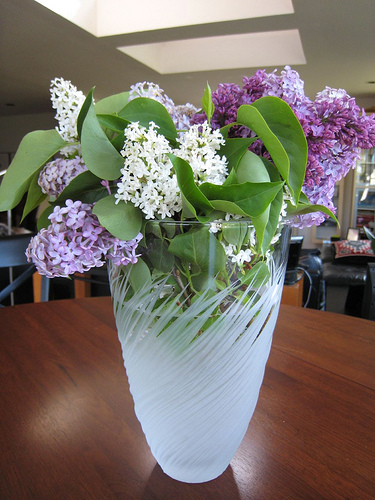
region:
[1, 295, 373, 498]
The table has a wooden top.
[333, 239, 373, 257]
Red designed pillow on black couch.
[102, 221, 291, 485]
The vase has frosted glass details.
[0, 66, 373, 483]
The vase is full of flowers.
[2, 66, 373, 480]
Purple and white flowers in a vase.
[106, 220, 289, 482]
The vase is made of glass.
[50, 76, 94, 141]
White flower sticking up in the back.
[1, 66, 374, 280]
The flowers have many green leaves.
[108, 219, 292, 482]
The vase in very large.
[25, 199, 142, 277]
Light purple flower to the front left.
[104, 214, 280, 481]
decorative frosted vase full of flowers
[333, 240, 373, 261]
decorative throw pillow sitting on chairs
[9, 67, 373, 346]
purple and white flowers sitting in vase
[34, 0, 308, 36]
sun shining trough huge skylight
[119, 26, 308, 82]
sun shining through large skylight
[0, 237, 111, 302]
black metal chair sitting near table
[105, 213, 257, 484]
frosted decorative vase sitting on table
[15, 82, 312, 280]
fresh green foilage laying in vase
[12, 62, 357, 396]
flowers in the vase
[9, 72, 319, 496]
flowers in the vase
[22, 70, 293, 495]
flowers in the vase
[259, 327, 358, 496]
a brown wooden table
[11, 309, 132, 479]
a brown wooden table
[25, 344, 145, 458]
a brown wooden table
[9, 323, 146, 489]
a brown wooden table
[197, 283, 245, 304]
Etched patter on a glass vase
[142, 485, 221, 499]
The shadow of a vase on a table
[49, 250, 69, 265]
Light purple lilac petals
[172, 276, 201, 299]
Leaves and stems inside a vase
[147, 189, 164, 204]
Small white flower petals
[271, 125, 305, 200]
Large green leaves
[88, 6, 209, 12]
Sky lights in a ceiling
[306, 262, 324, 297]
The black arm of a leather sofa or chair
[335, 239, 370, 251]
A small square patterned pillow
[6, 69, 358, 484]
flower pot on a table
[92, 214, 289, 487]
vase with water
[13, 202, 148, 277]
small purple flowers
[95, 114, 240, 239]
small white flowers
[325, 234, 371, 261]
a small red, grey, and white pillow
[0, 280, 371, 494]
a wooden table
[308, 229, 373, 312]
a black leather chair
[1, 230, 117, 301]
a black chair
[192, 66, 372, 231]
purple flowers on right side of glass flower pot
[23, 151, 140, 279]
purple flowers on left side of flower pot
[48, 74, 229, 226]
white flowers in the middle of flower pot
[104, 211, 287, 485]
glass flower pot on top of brown wooden table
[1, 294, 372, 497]
brown wooden table where flowers are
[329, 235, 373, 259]
black and red cushion on top of black couch